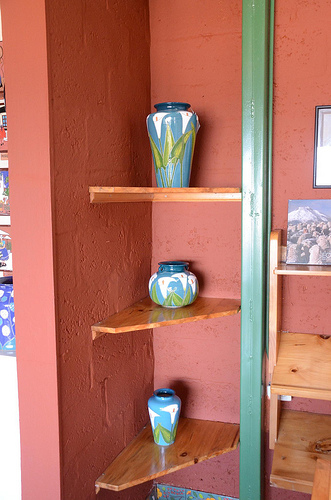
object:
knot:
[178, 450, 189, 458]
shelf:
[95, 409, 239, 490]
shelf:
[270, 325, 331, 407]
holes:
[59, 237, 122, 281]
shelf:
[88, 186, 242, 200]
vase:
[149, 260, 199, 309]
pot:
[146, 259, 200, 310]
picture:
[312, 106, 331, 186]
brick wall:
[2, 1, 331, 500]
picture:
[284, 199, 330, 265]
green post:
[239, 0, 277, 499]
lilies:
[150, 110, 167, 160]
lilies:
[174, 109, 191, 188]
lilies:
[157, 274, 174, 301]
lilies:
[168, 269, 189, 290]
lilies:
[160, 402, 179, 435]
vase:
[147, 387, 181, 445]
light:
[311, 141, 329, 186]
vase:
[145, 99, 200, 189]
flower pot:
[145, 101, 201, 189]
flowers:
[151, 109, 191, 186]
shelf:
[270, 261, 330, 274]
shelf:
[91, 296, 240, 341]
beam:
[238, 0, 276, 498]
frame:
[312, 103, 331, 189]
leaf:
[168, 129, 192, 163]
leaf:
[163, 121, 175, 169]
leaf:
[146, 132, 167, 173]